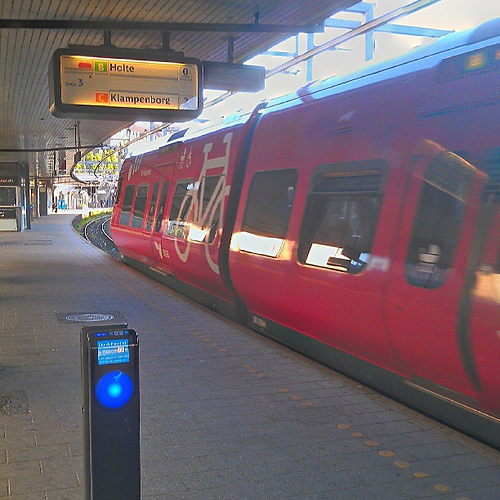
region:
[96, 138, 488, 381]
the train is red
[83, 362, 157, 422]
a blue led light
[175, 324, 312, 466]
the platform is paved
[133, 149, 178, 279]
train's door is closed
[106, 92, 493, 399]
train on a track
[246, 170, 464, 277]
window on the train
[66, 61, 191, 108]
lettering about train route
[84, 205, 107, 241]
track behind the train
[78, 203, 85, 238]
grass growing on track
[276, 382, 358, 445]
yellow dots on platform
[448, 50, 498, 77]
train lights on top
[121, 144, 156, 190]
graphics and lettering on train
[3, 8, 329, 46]
bar on roof over platform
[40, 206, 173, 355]
the platform is empty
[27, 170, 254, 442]
the platform is empty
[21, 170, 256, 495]
the platform is empty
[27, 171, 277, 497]
the platform is empty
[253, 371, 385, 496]
yellow dotted line on the ground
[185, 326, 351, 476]
yellow dotted line on the ground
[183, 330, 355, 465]
yellow dotted line on the ground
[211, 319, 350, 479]
yellow dotted line on the ground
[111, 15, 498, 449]
Red and black train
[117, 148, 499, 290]
Windows on a train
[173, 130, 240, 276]
Bicycle picture on train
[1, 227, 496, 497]
Bricks on a pavement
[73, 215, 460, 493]
Yellow mark on pavement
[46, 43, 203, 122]
Light hanging on ceiling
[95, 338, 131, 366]
Blue sticker on pole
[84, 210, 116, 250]
Metal tracks of train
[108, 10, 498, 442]
Train on train tracks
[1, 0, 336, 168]
Roof hanging over pavement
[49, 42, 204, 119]
sign hanging above train platform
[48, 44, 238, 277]
black and white sign over red train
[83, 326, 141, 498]
blue signs on black post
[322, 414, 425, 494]
yellow dots on sidewalk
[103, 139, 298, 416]
yellow dots on sidewalk by train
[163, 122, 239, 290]
white logo on red train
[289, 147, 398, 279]
tinted window on side of red train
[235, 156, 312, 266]
tinted window on side of red train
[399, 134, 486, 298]
tinted window on door of red train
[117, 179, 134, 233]
tinted window on side of red train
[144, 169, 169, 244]
tinted windows on doors of red train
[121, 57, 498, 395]
A red subway train.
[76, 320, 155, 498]
A grey post with blue stickers on it.